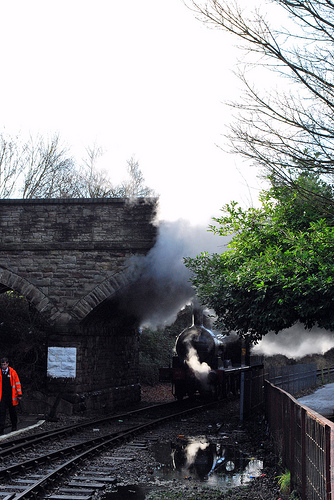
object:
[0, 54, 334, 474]
scene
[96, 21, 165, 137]
sky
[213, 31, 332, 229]
tree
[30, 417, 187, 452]
track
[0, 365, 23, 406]
jacket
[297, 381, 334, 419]
water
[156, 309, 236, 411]
train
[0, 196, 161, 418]
bridge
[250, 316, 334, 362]
steam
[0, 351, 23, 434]
man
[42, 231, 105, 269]
wall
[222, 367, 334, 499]
fence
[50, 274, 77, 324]
brick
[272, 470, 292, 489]
grass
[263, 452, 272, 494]
rocks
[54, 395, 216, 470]
railroad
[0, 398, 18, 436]
pant